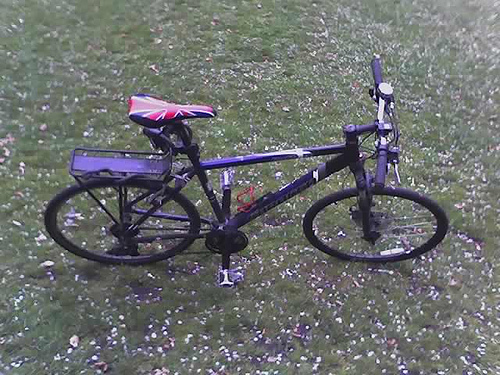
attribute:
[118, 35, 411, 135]
grass — brown, green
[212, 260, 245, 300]
pedal — metal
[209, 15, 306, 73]
grass — green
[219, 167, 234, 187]
pedal — metal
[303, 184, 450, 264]
tire — rubber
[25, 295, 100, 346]
grass — green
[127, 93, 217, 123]
flag — British